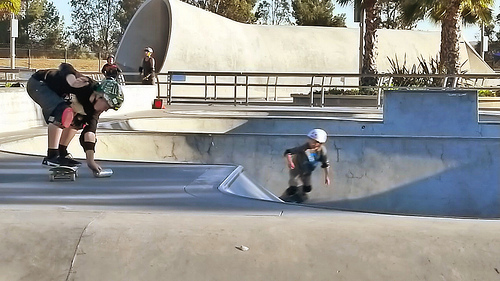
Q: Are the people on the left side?
A: Yes, the people are on the left of the image.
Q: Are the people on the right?
A: No, the people are on the left of the image.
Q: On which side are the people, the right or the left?
A: The people are on the left of the image.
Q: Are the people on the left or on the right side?
A: The people are on the left of the image.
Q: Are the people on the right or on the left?
A: The people are on the left of the image.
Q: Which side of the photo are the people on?
A: The people are on the left of the image.